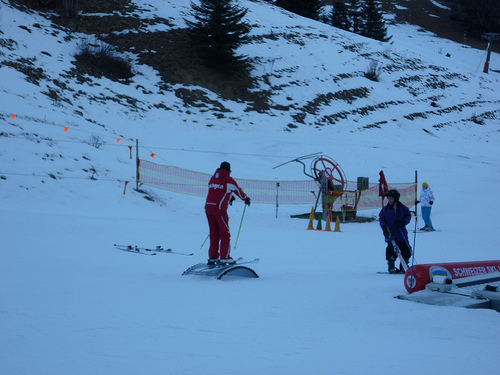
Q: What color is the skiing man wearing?
A: Red.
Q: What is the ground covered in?
A: Snow.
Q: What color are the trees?
A: Green.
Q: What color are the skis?
A: Silver.